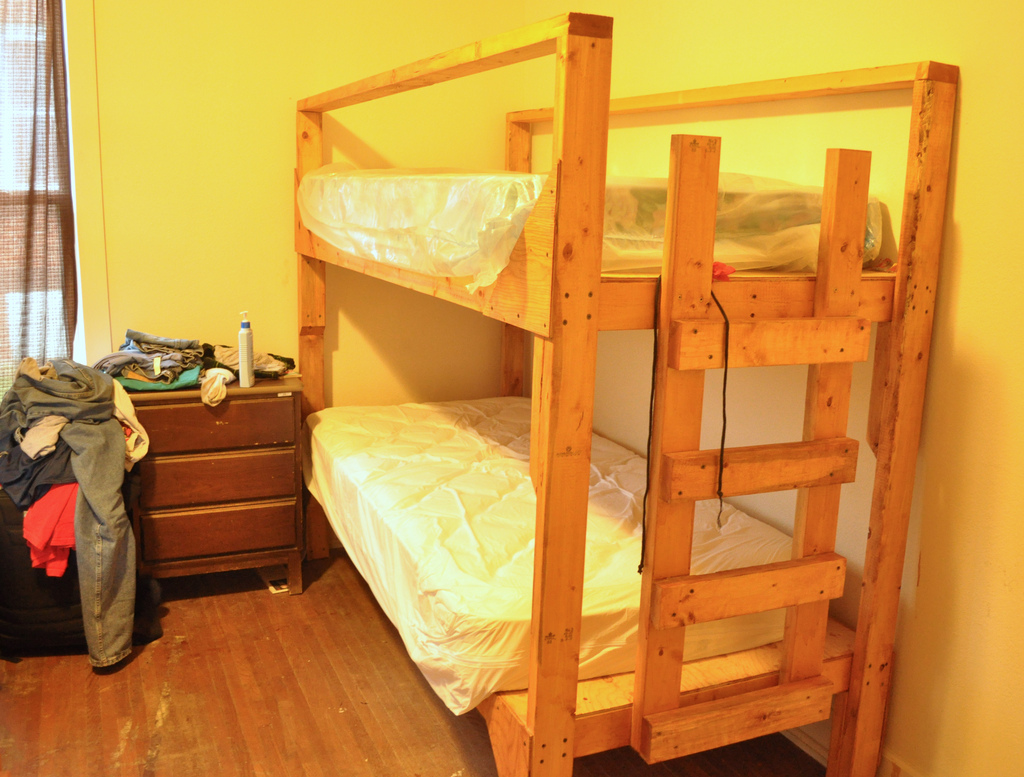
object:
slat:
[649, 551, 846, 631]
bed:
[293, 11, 959, 777]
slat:
[293, 111, 326, 560]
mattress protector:
[410, 611, 531, 717]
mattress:
[299, 396, 791, 718]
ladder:
[629, 134, 872, 765]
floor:
[0, 547, 835, 777]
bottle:
[239, 310, 256, 388]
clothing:
[0, 328, 296, 667]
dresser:
[120, 377, 303, 618]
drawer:
[134, 396, 296, 453]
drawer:
[140, 495, 298, 560]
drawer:
[139, 445, 297, 510]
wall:
[61, 0, 1024, 777]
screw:
[564, 293, 569, 299]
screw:
[588, 290, 594, 296]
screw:
[562, 319, 567, 326]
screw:
[586, 313, 591, 320]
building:
[0, 0, 1024, 776]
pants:
[0, 357, 137, 668]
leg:
[525, 12, 608, 775]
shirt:
[24, 482, 81, 576]